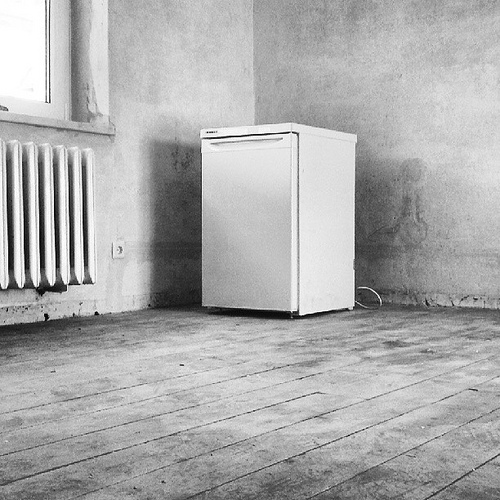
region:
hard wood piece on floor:
[110, 336, 370, 476]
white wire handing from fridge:
[357, 269, 400, 324]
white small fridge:
[189, 110, 359, 327]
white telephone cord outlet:
[101, 233, 132, 265]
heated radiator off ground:
[19, 138, 119, 295]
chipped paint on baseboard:
[396, 274, 493, 324]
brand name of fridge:
[201, 123, 231, 145]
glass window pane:
[7, 10, 40, 82]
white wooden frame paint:
[57, 15, 74, 117]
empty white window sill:
[5, 106, 147, 141]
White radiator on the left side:
[0, 128, 130, 310]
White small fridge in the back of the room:
[187, 100, 364, 330]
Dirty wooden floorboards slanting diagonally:
[105, 325, 401, 497]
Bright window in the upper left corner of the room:
[3, 23, 110, 128]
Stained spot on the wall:
[365, 101, 479, 293]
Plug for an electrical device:
[108, 237, 144, 282]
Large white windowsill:
[5, 105, 135, 142]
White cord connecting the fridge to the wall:
[345, 261, 393, 311]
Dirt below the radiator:
[3, 307, 107, 362]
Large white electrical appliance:
[180, 127, 356, 327]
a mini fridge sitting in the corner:
[198, 125, 360, 311]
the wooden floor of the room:
[7, 302, 499, 497]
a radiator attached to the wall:
[1, 139, 101, 289]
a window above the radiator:
[2, 0, 76, 115]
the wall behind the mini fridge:
[256, 2, 498, 314]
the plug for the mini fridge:
[353, 283, 383, 311]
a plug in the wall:
[111, 243, 126, 260]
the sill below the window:
[1, 109, 118, 141]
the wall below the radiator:
[1, 290, 81, 317]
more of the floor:
[163, 322, 280, 460]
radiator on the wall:
[3, 142, 101, 300]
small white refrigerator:
[161, 123, 418, 330]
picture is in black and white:
[22, 22, 499, 385]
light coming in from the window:
[12, 7, 115, 116]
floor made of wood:
[60, 354, 482, 491]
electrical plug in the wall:
[95, 227, 161, 277]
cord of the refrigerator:
[338, 277, 423, 329]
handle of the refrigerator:
[203, 136, 295, 146]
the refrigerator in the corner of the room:
[173, 76, 430, 326]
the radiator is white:
[14, 140, 113, 284]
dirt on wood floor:
[264, 446, 363, 488]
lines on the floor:
[153, 376, 271, 423]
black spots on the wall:
[33, 298, 61, 333]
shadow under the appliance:
[202, 302, 297, 332]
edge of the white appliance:
[207, 125, 297, 140]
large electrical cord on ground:
[342, 265, 392, 366]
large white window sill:
[18, 81, 115, 126]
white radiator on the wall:
[4, 130, 114, 300]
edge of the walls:
[206, 46, 287, 85]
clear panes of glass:
[21, 58, 56, 86]